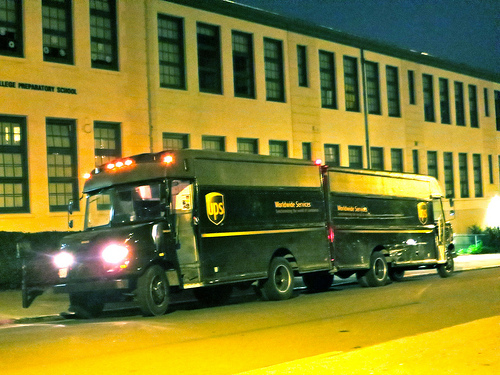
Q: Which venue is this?
A: This is a road.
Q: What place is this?
A: It is a road.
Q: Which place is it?
A: It is a road.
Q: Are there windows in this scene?
A: Yes, there is a window.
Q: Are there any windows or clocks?
A: Yes, there is a window.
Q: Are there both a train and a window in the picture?
A: No, there is a window but no trains.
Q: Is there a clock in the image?
A: No, there are no clocks.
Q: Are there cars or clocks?
A: No, there are no clocks or cars.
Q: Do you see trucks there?
A: Yes, there is a truck.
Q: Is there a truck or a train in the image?
A: Yes, there is a truck.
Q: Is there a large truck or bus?
A: Yes, there is a large truck.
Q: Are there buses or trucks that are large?
A: Yes, the truck is large.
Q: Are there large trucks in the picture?
A: Yes, there is a large truck.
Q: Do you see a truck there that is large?
A: Yes, there is a truck that is large.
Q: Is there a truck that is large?
A: Yes, there is a truck that is large.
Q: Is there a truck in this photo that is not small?
A: Yes, there is a large truck.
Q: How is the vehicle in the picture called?
A: The vehicle is a truck.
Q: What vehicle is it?
A: The vehicle is a truck.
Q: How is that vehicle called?
A: This is a truck.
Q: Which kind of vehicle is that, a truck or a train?
A: This is a truck.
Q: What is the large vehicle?
A: The vehicle is a truck.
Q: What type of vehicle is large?
A: The vehicle is a truck.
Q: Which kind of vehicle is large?
A: The vehicle is a truck.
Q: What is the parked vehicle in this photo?
A: The vehicle is a truck.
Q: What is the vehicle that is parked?
A: The vehicle is a truck.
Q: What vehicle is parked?
A: The vehicle is a truck.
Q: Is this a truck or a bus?
A: This is a truck.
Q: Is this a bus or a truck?
A: This is a truck.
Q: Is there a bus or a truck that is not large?
A: No, there is a truck but it is large.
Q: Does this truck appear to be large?
A: Yes, the truck is large.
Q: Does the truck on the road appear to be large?
A: Yes, the truck is large.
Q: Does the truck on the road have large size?
A: Yes, the truck is large.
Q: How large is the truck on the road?
A: The truck is large.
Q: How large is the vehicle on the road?
A: The truck is large.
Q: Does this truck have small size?
A: No, the truck is large.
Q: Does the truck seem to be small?
A: No, the truck is large.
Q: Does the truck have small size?
A: No, the truck is large.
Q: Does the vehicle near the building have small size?
A: No, the truck is large.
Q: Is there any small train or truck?
A: No, there is a truck but it is large.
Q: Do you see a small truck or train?
A: No, there is a truck but it is large.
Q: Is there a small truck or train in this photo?
A: No, there is a truck but it is large.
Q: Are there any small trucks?
A: No, there is a truck but it is large.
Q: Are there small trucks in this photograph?
A: No, there is a truck but it is large.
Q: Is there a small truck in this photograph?
A: No, there is a truck but it is large.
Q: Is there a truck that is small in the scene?
A: No, there is a truck but it is large.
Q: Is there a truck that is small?
A: No, there is a truck but it is large.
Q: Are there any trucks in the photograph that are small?
A: No, there is a truck but it is large.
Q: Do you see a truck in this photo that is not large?
A: No, there is a truck but it is large.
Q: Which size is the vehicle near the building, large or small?
A: The truck is large.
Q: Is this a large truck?
A: Yes, this is a large truck.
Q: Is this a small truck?
A: No, this is a large truck.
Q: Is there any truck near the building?
A: Yes, there is a truck near the building.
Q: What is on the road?
A: The truck is on the road.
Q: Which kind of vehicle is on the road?
A: The vehicle is a truck.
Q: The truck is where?
A: The truck is on the road.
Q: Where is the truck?
A: The truck is on the road.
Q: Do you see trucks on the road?
A: Yes, there is a truck on the road.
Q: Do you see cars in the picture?
A: No, there are no cars.